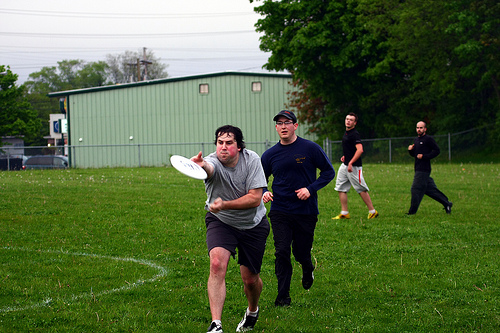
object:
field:
[26, 170, 498, 321]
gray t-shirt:
[200, 147, 267, 230]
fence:
[0, 119, 500, 171]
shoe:
[234, 310, 263, 332]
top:
[259, 134, 333, 215]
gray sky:
[0, 3, 287, 73]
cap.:
[272, 110, 297, 124]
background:
[0, 0, 500, 225]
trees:
[252, 0, 500, 166]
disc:
[170, 154, 209, 180]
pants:
[204, 211, 270, 273]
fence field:
[0, 145, 141, 170]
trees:
[0, 50, 109, 155]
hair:
[213, 125, 245, 151]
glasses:
[276, 121, 294, 125]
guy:
[189, 125, 270, 333]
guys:
[406, 121, 453, 216]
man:
[331, 111, 379, 219]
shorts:
[333, 159, 369, 192]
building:
[47, 70, 330, 169]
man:
[259, 109, 336, 306]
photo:
[0, 0, 500, 333]